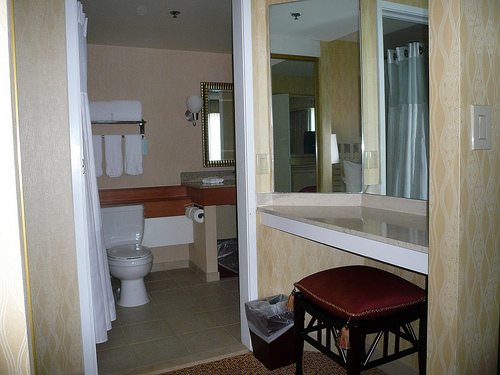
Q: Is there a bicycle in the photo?
A: No, there are no bicycles.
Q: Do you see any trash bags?
A: Yes, there is a trash bag.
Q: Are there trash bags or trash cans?
A: Yes, there is a trash bag.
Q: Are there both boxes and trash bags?
A: No, there is a trash bag but no boxes.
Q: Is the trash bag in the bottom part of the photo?
A: Yes, the trash bag is in the bottom of the image.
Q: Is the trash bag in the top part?
A: No, the trash bag is in the bottom of the image.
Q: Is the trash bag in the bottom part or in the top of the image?
A: The trash bag is in the bottom of the image.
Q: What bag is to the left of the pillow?
A: The bag is a trash bag.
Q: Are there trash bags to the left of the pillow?
A: Yes, there is a trash bag to the left of the pillow.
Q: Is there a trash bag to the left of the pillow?
A: Yes, there is a trash bag to the left of the pillow.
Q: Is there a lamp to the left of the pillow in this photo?
A: No, there is a trash bag to the left of the pillow.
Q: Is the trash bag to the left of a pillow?
A: Yes, the trash bag is to the left of a pillow.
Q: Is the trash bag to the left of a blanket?
A: No, the trash bag is to the left of a pillow.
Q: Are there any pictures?
A: No, there are no pictures.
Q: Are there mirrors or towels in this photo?
A: Yes, there is a towel.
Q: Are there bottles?
A: No, there are no bottles.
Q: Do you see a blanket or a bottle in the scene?
A: No, there are no bottles or blankets.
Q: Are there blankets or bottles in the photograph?
A: No, there are no bottles or blankets.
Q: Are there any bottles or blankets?
A: No, there are no bottles or blankets.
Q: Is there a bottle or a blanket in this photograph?
A: No, there are no bottles or blankets.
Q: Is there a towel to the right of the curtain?
A: Yes, there is a towel to the right of the curtain.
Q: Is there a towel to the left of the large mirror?
A: Yes, there is a towel to the left of the mirror.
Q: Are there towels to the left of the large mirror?
A: Yes, there is a towel to the left of the mirror.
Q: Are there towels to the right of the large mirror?
A: No, the towel is to the left of the mirror.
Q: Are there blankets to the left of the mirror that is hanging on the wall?
A: No, there is a towel to the left of the mirror.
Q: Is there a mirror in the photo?
A: Yes, there is a mirror.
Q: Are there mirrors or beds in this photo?
A: Yes, there is a mirror.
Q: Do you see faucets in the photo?
A: No, there are no faucets.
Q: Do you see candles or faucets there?
A: No, there are no faucets or candles.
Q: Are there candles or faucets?
A: No, there are no faucets or candles.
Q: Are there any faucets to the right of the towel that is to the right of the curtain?
A: No, there is a mirror to the right of the towel.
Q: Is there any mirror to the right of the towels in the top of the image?
A: Yes, there is a mirror to the right of the towels.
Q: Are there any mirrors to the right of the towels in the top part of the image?
A: Yes, there is a mirror to the right of the towels.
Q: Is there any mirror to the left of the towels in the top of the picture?
A: No, the mirror is to the right of the towels.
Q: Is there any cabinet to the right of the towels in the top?
A: No, there is a mirror to the right of the towels.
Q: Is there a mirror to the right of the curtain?
A: Yes, there is a mirror to the right of the curtain.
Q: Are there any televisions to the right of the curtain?
A: No, there is a mirror to the right of the curtain.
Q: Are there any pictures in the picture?
A: No, there are no pictures.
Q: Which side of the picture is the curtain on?
A: The curtain is on the left of the image.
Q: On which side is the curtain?
A: The curtain is on the left of the image.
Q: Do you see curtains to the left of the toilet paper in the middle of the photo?
A: Yes, there is a curtain to the left of the toilet paper.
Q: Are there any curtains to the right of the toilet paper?
A: No, the curtain is to the left of the toilet paper.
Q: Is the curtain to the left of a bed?
A: No, the curtain is to the left of a toilet paper.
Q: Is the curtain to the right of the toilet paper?
A: No, the curtain is to the left of the toilet paper.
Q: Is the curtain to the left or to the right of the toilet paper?
A: The curtain is to the left of the toilet paper.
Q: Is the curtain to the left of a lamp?
A: No, the curtain is to the left of a towel.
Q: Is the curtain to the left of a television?
A: No, the curtain is to the left of a mirror.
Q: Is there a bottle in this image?
A: No, there are no bottles.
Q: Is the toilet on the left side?
A: Yes, the toilet is on the left of the image.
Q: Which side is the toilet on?
A: The toilet is on the left of the image.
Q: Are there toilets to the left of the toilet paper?
A: Yes, there is a toilet to the left of the toilet paper.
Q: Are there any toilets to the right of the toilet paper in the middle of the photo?
A: No, the toilet is to the left of the toilet paper.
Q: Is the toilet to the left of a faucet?
A: No, the toilet is to the left of the toilet paper.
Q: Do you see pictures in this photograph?
A: No, there are no pictures.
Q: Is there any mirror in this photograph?
A: Yes, there is a mirror.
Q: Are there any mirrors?
A: Yes, there is a mirror.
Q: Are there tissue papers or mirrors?
A: Yes, there is a mirror.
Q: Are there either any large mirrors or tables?
A: Yes, there is a large mirror.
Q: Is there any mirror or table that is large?
A: Yes, the mirror is large.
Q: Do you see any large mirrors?
A: Yes, there is a large mirror.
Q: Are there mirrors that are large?
A: Yes, there is a mirror that is large.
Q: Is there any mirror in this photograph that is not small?
A: Yes, there is a large mirror.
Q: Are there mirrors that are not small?
A: Yes, there is a large mirror.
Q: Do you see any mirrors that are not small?
A: Yes, there is a large mirror.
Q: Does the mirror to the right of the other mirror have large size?
A: Yes, the mirror is large.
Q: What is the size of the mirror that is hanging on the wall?
A: The mirror is large.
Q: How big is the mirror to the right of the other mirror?
A: The mirror is large.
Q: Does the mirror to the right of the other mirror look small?
A: No, the mirror is large.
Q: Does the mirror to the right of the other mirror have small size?
A: No, the mirror is large.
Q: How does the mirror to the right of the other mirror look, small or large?
A: The mirror is large.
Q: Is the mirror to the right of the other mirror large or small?
A: The mirror is large.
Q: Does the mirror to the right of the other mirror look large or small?
A: The mirror is large.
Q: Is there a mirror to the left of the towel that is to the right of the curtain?
A: No, the mirror is to the right of the towel.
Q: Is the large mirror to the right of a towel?
A: Yes, the mirror is to the right of a towel.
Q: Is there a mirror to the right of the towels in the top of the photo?
A: Yes, there is a mirror to the right of the towels.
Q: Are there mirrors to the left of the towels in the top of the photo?
A: No, the mirror is to the right of the towels.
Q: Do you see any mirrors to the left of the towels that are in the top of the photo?
A: No, the mirror is to the right of the towels.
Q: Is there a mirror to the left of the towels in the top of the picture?
A: No, the mirror is to the right of the towels.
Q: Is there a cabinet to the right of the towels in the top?
A: No, there is a mirror to the right of the towels.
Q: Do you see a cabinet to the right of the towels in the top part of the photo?
A: No, there is a mirror to the right of the towels.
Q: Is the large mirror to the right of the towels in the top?
A: Yes, the mirror is to the right of the towels.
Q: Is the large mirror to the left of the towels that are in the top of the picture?
A: No, the mirror is to the right of the towels.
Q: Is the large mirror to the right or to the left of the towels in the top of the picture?
A: The mirror is to the right of the towels.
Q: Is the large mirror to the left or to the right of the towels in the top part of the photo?
A: The mirror is to the right of the towels.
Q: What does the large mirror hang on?
A: The mirror hangs on the wall.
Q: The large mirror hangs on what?
A: The mirror hangs on the wall.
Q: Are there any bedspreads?
A: No, there are no bedspreads.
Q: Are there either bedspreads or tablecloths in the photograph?
A: No, there are no bedspreads or tablecloths.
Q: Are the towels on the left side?
A: Yes, the towels are on the left of the image.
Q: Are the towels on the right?
A: No, the towels are on the left of the image.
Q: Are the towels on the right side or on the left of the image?
A: The towels are on the left of the image.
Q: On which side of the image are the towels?
A: The towels are on the left of the image.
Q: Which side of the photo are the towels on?
A: The towels are on the left of the image.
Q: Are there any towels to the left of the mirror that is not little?
A: Yes, there are towels to the left of the mirror.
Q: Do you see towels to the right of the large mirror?
A: No, the towels are to the left of the mirror.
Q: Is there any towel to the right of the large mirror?
A: No, the towels are to the left of the mirror.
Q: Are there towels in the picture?
A: Yes, there is a towel.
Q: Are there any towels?
A: Yes, there is a towel.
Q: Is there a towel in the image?
A: Yes, there is a towel.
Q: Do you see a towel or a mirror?
A: Yes, there is a towel.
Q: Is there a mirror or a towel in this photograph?
A: Yes, there is a towel.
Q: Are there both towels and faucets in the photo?
A: No, there is a towel but no faucets.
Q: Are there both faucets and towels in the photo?
A: No, there is a towel but no faucets.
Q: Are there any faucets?
A: No, there are no faucets.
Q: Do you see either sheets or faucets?
A: No, there are no faucets or sheets.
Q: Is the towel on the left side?
A: Yes, the towel is on the left of the image.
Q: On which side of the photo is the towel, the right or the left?
A: The towel is on the left of the image.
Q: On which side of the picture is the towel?
A: The towel is on the left of the image.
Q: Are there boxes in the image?
A: No, there are no boxes.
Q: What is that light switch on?
A: The light switch is on the wall.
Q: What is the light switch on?
A: The light switch is on the wall.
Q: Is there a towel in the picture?
A: Yes, there is a towel.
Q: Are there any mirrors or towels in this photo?
A: Yes, there is a towel.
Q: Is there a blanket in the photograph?
A: No, there are no blankets.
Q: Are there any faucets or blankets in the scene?
A: No, there are no blankets or faucets.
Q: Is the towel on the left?
A: Yes, the towel is on the left of the image.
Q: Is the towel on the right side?
A: No, the towel is on the left of the image.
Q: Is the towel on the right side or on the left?
A: The towel is on the left of the image.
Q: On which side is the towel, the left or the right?
A: The towel is on the left of the image.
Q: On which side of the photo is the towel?
A: The towel is on the left of the image.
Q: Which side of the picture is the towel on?
A: The towel is on the left of the image.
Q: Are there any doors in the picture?
A: Yes, there is a door.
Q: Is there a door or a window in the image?
A: Yes, there is a door.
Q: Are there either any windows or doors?
A: Yes, there is a door.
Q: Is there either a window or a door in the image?
A: Yes, there is a door.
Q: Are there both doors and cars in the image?
A: No, there is a door but no cars.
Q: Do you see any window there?
A: No, there are no windows.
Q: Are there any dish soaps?
A: No, there are no dish soaps.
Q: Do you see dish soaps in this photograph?
A: No, there are no dish soaps.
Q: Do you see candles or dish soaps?
A: No, there are no dish soaps or candles.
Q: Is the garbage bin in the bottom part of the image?
A: Yes, the garbage bin is in the bottom of the image.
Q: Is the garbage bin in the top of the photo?
A: No, the garbage bin is in the bottom of the image.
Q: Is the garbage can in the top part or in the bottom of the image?
A: The garbage can is in the bottom of the image.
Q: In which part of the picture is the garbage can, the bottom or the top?
A: The garbage can is in the bottom of the image.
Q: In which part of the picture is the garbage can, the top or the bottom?
A: The garbage can is in the bottom of the image.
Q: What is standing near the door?
A: The trash bin is standing near the door.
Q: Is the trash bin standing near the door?
A: Yes, the trash bin is standing near the door.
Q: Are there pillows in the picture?
A: Yes, there is a pillow.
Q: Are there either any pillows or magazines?
A: Yes, there is a pillow.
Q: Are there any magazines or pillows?
A: Yes, there is a pillow.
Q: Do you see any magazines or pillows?
A: Yes, there is a pillow.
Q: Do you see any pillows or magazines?
A: Yes, there is a pillow.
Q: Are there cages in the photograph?
A: No, there are no cages.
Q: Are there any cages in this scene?
A: No, there are no cages.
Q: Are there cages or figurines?
A: No, there are no cages or figurines.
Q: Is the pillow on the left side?
A: No, the pillow is on the right of the image.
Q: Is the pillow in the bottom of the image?
A: Yes, the pillow is in the bottom of the image.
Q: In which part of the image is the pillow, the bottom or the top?
A: The pillow is in the bottom of the image.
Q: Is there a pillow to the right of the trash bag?
A: Yes, there is a pillow to the right of the trash bag.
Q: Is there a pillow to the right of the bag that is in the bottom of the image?
A: Yes, there is a pillow to the right of the trash bag.